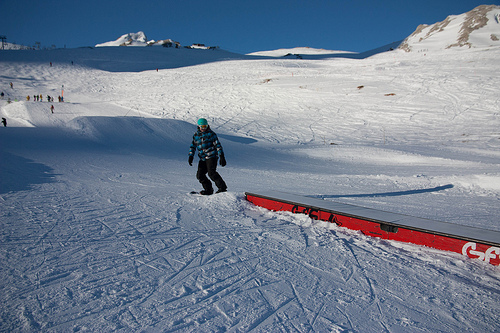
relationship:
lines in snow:
[1, 60, 499, 331] [0, 1, 500, 333]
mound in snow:
[399, 1, 500, 54] [0, 1, 500, 333]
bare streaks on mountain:
[395, 7, 487, 52] [365, 1, 499, 57]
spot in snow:
[354, 82, 368, 93] [0, 1, 500, 333]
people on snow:
[2, 51, 242, 207] [0, 1, 500, 333]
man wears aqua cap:
[180, 110, 231, 201] [197, 118, 209, 130]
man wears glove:
[180, 110, 231, 201] [187, 154, 195, 168]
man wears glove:
[180, 110, 231, 201] [217, 152, 229, 169]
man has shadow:
[180, 110, 231, 201] [303, 176, 462, 203]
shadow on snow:
[303, 176, 462, 203] [0, 1, 500, 333]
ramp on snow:
[243, 186, 500, 267] [0, 1, 500, 333]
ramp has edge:
[243, 186, 500, 267] [244, 183, 499, 249]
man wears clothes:
[180, 110, 231, 201] [190, 124, 226, 189]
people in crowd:
[0, 77, 73, 138] [2, 80, 68, 133]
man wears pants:
[180, 110, 231, 201] [194, 161, 228, 191]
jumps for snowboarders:
[1, 73, 238, 161] [0, 74, 238, 218]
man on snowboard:
[180, 110, 231, 201] [187, 188, 211, 199]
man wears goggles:
[187, 117, 228, 194] [197, 124, 208, 129]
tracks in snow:
[3, 187, 498, 332] [0, 1, 500, 333]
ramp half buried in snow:
[245, 183, 499, 279] [198, 201, 499, 268]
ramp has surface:
[245, 183, 499, 279] [245, 187, 499, 247]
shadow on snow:
[0, 112, 347, 163] [0, 1, 500, 333]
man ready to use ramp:
[187, 117, 228, 194] [245, 183, 499, 279]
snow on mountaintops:
[0, 1, 500, 333] [88, 27, 212, 51]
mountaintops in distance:
[88, 27, 212, 51] [0, 0, 499, 77]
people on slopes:
[0, 77, 73, 138] [2, 51, 242, 207]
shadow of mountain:
[1, 38, 402, 82] [1, 49, 6, 60]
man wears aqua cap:
[187, 117, 228, 194] [195, 115, 212, 125]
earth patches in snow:
[252, 68, 402, 149] [0, 1, 500, 333]